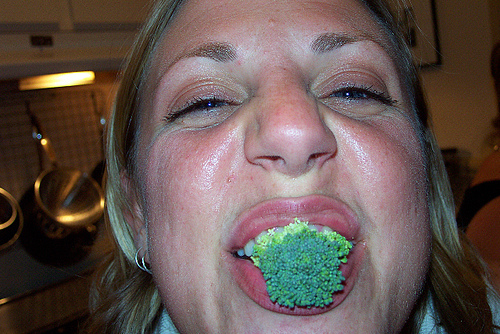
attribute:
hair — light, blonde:
[96, 4, 498, 327]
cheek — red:
[366, 138, 419, 220]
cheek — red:
[150, 125, 225, 254]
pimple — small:
[268, 16, 278, 28]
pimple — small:
[223, 169, 237, 184]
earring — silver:
[126, 241, 167, 282]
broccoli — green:
[243, 215, 356, 315]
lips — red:
[221, 192, 366, 318]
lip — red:
[228, 194, 363, 250]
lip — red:
[224, 239, 365, 315]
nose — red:
[229, 72, 356, 193]